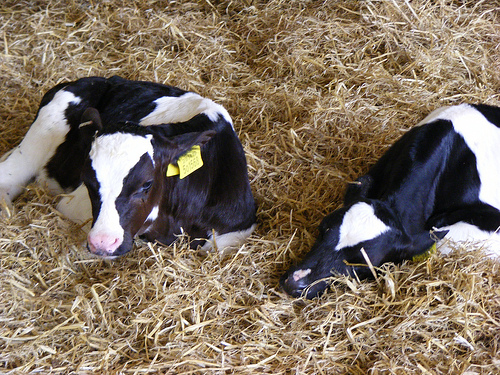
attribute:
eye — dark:
[136, 177, 153, 193]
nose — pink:
[89, 230, 119, 250]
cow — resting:
[1, 74, 259, 260]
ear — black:
[153, 131, 210, 165]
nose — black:
[278, 271, 323, 302]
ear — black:
[405, 216, 446, 266]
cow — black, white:
[281, 83, 499, 323]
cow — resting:
[4, 64, 262, 284]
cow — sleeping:
[270, 94, 490, 324]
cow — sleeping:
[260, 89, 499, 309]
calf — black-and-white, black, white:
[4, 68, 260, 279]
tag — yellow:
[168, 146, 208, 183]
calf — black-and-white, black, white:
[277, 81, 497, 307]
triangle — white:
[324, 197, 400, 257]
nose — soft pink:
[81, 229, 121, 264]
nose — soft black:
[274, 263, 312, 308]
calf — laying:
[284, 95, 495, 300]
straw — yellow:
[1, 0, 497, 373]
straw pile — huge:
[0, 2, 500, 372]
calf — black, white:
[280, 135, 483, 288]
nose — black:
[284, 269, 306, 301]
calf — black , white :
[69, 171, 129, 279]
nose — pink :
[64, 207, 182, 295]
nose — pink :
[67, 203, 129, 281]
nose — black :
[287, 248, 338, 322]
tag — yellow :
[147, 124, 224, 197]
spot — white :
[315, 176, 395, 272]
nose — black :
[286, 174, 399, 334]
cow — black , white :
[242, 68, 471, 342]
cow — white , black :
[40, 70, 285, 288]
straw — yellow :
[37, 227, 473, 367]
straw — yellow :
[29, 210, 452, 365]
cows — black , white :
[39, 40, 475, 319]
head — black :
[60, 116, 171, 250]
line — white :
[134, 90, 162, 196]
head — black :
[231, 143, 427, 349]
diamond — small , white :
[317, 179, 408, 269]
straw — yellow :
[58, 251, 394, 360]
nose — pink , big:
[69, 177, 151, 295]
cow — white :
[29, 68, 302, 290]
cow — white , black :
[291, 107, 446, 323]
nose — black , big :
[246, 212, 393, 361]